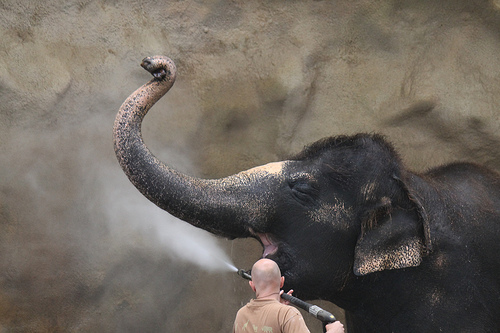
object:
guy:
[232, 257, 343, 333]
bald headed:
[251, 258, 281, 293]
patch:
[204, 159, 291, 186]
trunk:
[114, 56, 240, 230]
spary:
[76, 134, 237, 274]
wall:
[0, 0, 500, 333]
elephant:
[112, 55, 500, 333]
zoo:
[0, 0, 500, 333]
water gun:
[235, 269, 337, 333]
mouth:
[248, 226, 278, 267]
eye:
[287, 177, 320, 200]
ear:
[353, 175, 434, 276]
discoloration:
[356, 240, 421, 276]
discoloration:
[308, 194, 355, 230]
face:
[235, 153, 361, 301]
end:
[140, 56, 176, 80]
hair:
[292, 131, 403, 164]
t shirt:
[234, 299, 308, 333]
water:
[62, 139, 238, 276]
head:
[111, 56, 402, 303]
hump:
[425, 160, 500, 181]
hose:
[239, 271, 337, 333]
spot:
[243, 159, 297, 179]